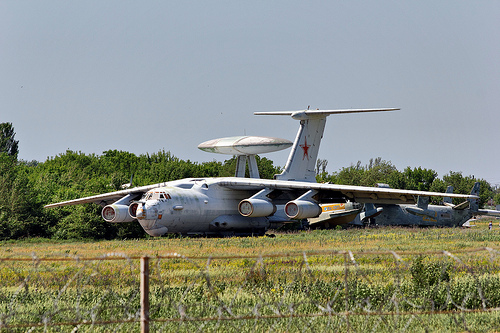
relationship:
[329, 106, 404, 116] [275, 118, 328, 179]
left wing by tail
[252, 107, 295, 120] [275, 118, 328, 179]
right wing by tail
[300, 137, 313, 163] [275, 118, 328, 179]
star on side of tail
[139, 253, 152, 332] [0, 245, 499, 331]
post attached to barb wire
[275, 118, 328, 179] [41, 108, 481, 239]
tail of plane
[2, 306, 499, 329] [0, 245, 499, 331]
barb wire attached to barb wire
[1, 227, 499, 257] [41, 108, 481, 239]
grass area near plane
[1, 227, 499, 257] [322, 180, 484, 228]
grass area near plane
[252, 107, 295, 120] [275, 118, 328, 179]
wing of tail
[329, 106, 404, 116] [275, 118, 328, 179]
wing of tail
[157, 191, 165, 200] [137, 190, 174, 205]
window of cockpit area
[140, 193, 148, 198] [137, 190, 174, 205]
window of cockpit area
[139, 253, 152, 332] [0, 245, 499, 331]
post of barb wire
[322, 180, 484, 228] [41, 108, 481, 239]
plane behind jet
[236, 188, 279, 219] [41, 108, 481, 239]
engine affixed to plane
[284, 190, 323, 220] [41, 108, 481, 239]
engine affixed to plane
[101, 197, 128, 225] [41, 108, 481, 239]
engine affixed to plane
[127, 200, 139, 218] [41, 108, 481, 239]
engine affixed to plane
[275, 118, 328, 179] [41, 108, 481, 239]
tail of a plane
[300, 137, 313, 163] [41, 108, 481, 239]
red star on side of plane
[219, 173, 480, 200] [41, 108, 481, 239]
wing of a plane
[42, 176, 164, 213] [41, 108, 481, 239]
wing of a plane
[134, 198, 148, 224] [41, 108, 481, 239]
nose of a plane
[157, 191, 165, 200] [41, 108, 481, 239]
window of a plane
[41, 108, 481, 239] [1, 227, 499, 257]
airplane on top of ground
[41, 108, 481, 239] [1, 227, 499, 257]
airplane sits on top of ground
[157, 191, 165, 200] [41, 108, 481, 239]
window of an airplane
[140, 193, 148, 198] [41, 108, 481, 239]
window of an airplane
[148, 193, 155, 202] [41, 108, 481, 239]
window of an airplane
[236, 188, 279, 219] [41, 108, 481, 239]
engine to an airplane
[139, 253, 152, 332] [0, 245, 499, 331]
pole support for a barb wire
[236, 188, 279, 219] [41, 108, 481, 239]
jet engine to plane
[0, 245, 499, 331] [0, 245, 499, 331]
barb wire attached to barb wire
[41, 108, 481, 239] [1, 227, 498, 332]
plane on top of field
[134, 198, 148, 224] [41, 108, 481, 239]
nose of a jet plane